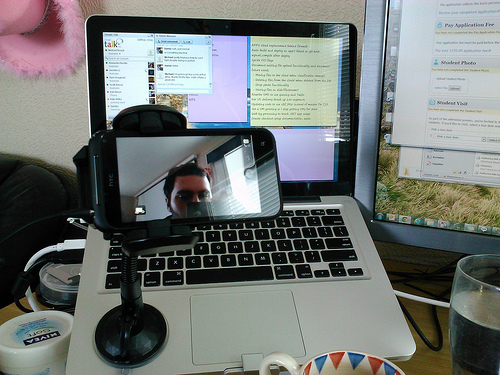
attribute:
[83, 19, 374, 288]
computer — laptop, black, white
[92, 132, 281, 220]
phone — mounted, mobilephone, black, cellphone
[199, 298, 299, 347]
touchpad — trackpad, grey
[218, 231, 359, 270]
keyboard — black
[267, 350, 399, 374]
mug — colorful, decorated, white, blue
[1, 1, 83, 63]
hat — pink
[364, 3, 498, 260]
monitor — large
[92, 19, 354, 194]
screen — black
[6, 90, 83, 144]
wall — white, cream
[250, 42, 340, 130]
sitcikynote — stickynote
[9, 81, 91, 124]
plasterwall — white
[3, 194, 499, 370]
desk — brown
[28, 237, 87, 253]
cord — white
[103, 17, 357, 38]
frame — black